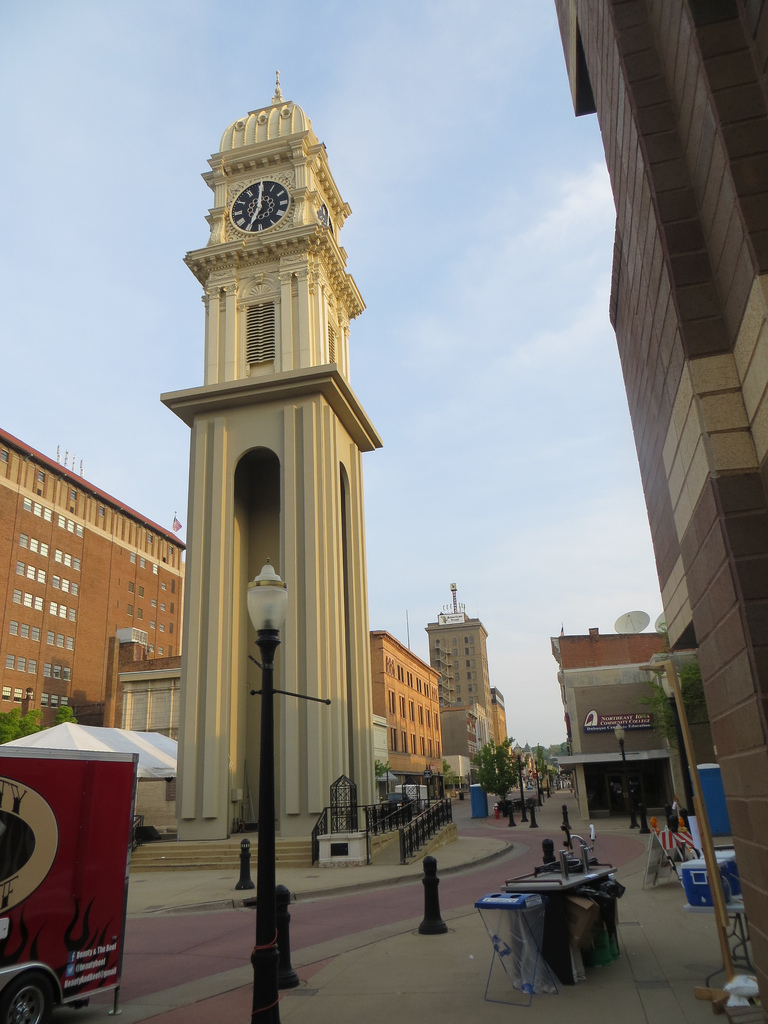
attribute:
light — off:
[192, 534, 344, 652]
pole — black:
[253, 754, 307, 883]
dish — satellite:
[601, 596, 673, 646]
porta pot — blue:
[450, 774, 498, 814]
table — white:
[675, 889, 747, 942]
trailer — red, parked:
[52, 760, 107, 956]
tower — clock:
[167, 518, 391, 805]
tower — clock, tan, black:
[143, 159, 416, 774]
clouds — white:
[502, 233, 577, 379]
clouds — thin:
[460, 237, 524, 372]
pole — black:
[206, 635, 300, 954]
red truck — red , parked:
[6, 740, 163, 1020]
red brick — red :
[162, 899, 224, 966]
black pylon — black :
[393, 844, 451, 966]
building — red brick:
[9, 435, 204, 814]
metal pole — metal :
[402, 829, 464, 957]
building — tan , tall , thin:
[419, 582, 519, 777]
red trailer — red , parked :
[0, 723, 157, 1009]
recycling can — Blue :
[472, 878, 552, 1009]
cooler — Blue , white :
[665, 836, 758, 928]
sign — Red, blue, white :
[569, 698, 673, 752]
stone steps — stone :
[122, 833, 339, 874]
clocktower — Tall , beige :
[155, 68, 393, 879]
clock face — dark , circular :
[222, 177, 301, 238]